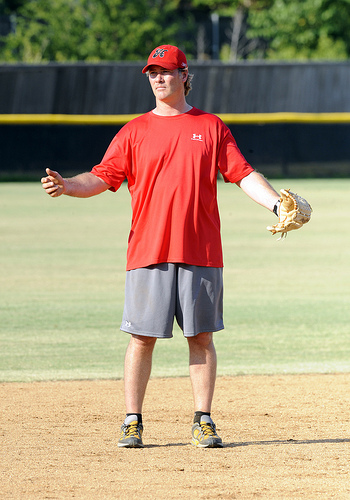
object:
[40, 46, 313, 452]
man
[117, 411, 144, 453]
shoes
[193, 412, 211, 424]
socks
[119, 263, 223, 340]
shorts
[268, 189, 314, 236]
glove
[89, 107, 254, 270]
shirt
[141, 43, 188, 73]
cap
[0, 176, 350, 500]
field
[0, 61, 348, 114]
wall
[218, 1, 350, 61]
trees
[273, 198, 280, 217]
watch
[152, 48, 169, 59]
logo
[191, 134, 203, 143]
logo